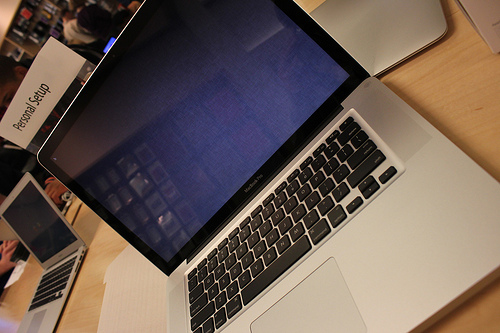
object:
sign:
[0, 36, 88, 150]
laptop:
[0, 171, 88, 332]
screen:
[36, 0, 371, 278]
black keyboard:
[187, 116, 398, 332]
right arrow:
[379, 166, 398, 184]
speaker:
[354, 88, 430, 162]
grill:
[354, 85, 433, 162]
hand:
[0, 239, 19, 277]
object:
[0, 240, 31, 263]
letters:
[244, 174, 263, 192]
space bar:
[241, 235, 312, 306]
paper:
[96, 244, 192, 333]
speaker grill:
[166, 279, 189, 332]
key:
[308, 218, 331, 245]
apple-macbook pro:
[37, 0, 499, 332]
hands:
[45, 177, 68, 205]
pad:
[249, 257, 366, 333]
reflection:
[49, 0, 353, 262]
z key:
[215, 291, 227, 310]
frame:
[36, 1, 372, 278]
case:
[309, 0, 449, 78]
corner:
[103, 263, 122, 284]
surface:
[0, 0, 499, 333]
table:
[0, 1, 499, 333]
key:
[190, 301, 215, 331]